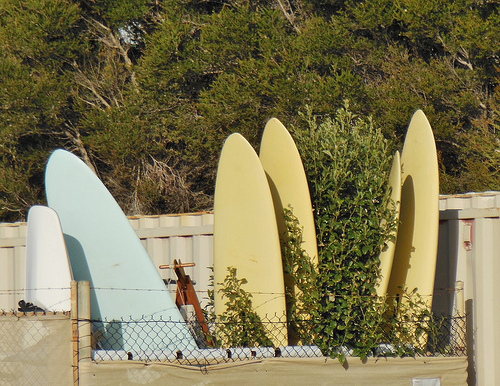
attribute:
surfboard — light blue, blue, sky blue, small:
[45, 153, 196, 358]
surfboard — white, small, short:
[19, 204, 74, 313]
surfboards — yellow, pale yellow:
[215, 113, 318, 349]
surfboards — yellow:
[373, 97, 447, 344]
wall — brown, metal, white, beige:
[2, 169, 498, 347]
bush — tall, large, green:
[297, 104, 387, 346]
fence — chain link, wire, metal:
[0, 283, 476, 378]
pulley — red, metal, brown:
[163, 257, 220, 356]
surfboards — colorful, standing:
[15, 98, 447, 355]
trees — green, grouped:
[1, 4, 497, 203]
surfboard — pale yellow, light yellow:
[212, 135, 290, 352]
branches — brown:
[64, 15, 499, 209]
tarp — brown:
[3, 314, 468, 385]